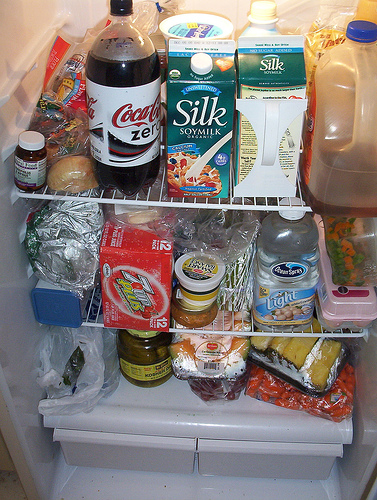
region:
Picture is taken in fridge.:
[15, 8, 369, 498]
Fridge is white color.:
[8, 8, 357, 478]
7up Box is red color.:
[96, 245, 175, 345]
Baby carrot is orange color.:
[257, 372, 350, 419]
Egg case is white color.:
[318, 262, 375, 332]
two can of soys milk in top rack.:
[162, 53, 305, 202]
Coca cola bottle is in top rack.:
[79, 53, 162, 215]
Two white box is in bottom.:
[49, 425, 371, 492]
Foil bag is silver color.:
[30, 208, 101, 281]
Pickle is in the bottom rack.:
[117, 329, 169, 389]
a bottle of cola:
[69, 3, 167, 189]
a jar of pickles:
[105, 323, 176, 389]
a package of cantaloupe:
[168, 334, 243, 378]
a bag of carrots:
[237, 367, 351, 418]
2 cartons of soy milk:
[163, 31, 299, 196]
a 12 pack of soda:
[85, 216, 177, 336]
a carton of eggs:
[310, 215, 370, 323]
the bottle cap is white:
[265, 196, 304, 221]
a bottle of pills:
[10, 120, 43, 193]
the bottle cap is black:
[103, 0, 139, 19]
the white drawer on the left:
[54, 434, 199, 467]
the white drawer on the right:
[199, 430, 341, 481]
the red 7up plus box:
[100, 217, 169, 330]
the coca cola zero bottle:
[92, 8, 161, 183]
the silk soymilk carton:
[164, 34, 232, 199]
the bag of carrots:
[249, 367, 361, 416]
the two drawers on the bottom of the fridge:
[45, 422, 344, 480]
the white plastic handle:
[233, 93, 301, 205]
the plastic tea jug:
[304, 19, 375, 218]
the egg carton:
[313, 217, 374, 336]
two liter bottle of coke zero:
[83, 3, 162, 193]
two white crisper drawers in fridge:
[35, 413, 360, 495]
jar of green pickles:
[111, 329, 175, 394]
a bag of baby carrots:
[241, 361, 287, 410]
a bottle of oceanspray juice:
[257, 209, 317, 333]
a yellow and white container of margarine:
[176, 249, 230, 308]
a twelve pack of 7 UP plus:
[93, 236, 175, 344]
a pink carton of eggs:
[312, 281, 371, 326]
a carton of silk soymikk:
[159, 33, 245, 204]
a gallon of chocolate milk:
[304, 32, 373, 214]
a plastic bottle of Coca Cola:
[86, 0, 160, 195]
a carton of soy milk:
[165, 34, 229, 193]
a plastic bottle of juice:
[300, 18, 370, 211]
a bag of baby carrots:
[334, 362, 350, 415]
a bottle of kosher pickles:
[114, 325, 168, 384]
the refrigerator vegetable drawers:
[41, 405, 352, 481]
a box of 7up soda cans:
[97, 219, 167, 326]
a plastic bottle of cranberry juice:
[252, 200, 317, 329]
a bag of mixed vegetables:
[319, 211, 373, 282]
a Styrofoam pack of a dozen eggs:
[318, 285, 375, 329]